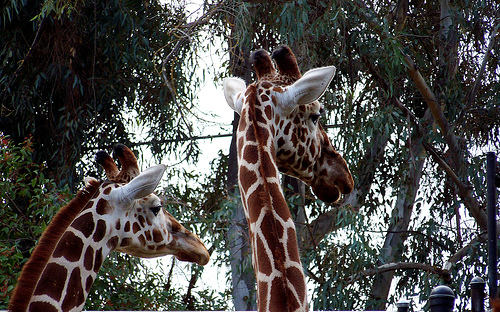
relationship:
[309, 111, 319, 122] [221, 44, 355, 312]
eye on giraffe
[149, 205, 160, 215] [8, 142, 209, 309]
eye on giraffe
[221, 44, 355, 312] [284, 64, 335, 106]
giraffe has ear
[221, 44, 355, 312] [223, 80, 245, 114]
giraffe has ear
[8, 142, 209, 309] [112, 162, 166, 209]
giraffe has ear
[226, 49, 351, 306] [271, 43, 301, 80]
giraffe has horn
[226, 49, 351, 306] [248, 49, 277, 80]
giraffe has horn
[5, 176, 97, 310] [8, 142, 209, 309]
mane on giraffe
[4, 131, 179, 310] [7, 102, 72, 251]
flowers on bushes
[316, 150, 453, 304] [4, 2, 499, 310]
fence surrounding area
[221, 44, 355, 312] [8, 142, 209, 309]
giraffe next to giraffe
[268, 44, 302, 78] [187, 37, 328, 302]
horn on giraffe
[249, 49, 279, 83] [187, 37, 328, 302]
horn on giraffe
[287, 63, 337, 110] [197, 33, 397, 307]
ear on giraffe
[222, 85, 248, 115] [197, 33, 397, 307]
ear on giraffe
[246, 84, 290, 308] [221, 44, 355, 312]
mane on giraffe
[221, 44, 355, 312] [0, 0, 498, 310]
giraffe eating leaves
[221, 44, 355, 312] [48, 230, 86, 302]
giraffe have spots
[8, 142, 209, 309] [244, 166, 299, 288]
giraffe have spots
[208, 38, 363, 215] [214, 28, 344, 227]
head on giraffe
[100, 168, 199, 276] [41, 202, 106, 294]
head on giraffe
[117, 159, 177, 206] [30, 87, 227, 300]
ear of a giraffe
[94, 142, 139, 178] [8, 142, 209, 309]
horns of a giraffe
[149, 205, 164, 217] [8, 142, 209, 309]
eye of a giraffe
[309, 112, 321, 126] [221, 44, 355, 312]
eye of a giraffe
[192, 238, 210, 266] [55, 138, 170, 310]
giraffe nose of a giraffe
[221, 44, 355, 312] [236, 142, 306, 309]
giraffe have neck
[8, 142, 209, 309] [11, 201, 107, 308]
giraffe have neck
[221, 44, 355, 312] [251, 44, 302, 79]
giraffe have horn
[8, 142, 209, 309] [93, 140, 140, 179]
giraffe have horn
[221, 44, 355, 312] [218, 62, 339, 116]
giraffe has ears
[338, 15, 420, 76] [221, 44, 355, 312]
two necks of a giraffe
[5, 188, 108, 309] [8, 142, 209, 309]
necks of a giraffe